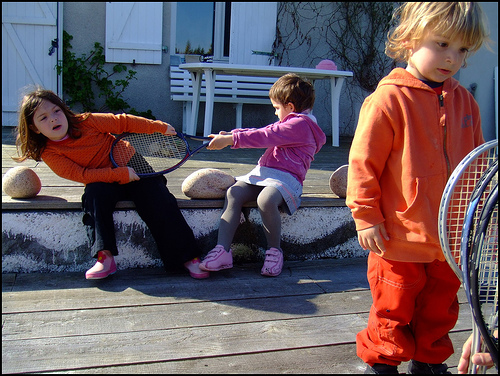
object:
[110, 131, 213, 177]
tennis racket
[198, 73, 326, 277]
girl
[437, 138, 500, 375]
tennis racket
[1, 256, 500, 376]
walkway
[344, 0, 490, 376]
boy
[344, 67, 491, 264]
jacket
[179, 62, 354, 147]
table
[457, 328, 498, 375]
hand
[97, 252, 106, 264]
flower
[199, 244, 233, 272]
boots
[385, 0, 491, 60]
hair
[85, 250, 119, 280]
sports shoes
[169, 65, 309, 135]
bench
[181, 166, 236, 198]
stone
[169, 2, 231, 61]
window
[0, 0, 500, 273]
background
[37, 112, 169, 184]
shirt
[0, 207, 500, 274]
step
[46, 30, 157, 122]
plant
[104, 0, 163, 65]
shutter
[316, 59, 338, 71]
tap light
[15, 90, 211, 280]
girl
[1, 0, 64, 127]
gate